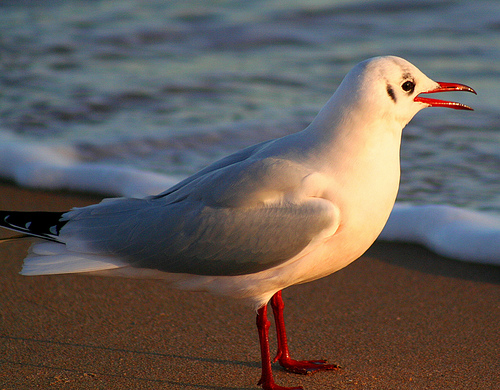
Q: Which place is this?
A: It is an ocean.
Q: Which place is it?
A: It is an ocean.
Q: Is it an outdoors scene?
A: Yes, it is outdoors.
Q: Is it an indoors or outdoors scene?
A: It is outdoors.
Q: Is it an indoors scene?
A: No, it is outdoors.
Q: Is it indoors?
A: No, it is outdoors.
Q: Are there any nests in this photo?
A: No, there are no nests.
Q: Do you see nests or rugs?
A: No, there are no nests or rugs.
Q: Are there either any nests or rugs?
A: No, there are no nests or rugs.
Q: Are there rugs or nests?
A: No, there are no nests or rugs.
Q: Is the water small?
A: Yes, the water is small.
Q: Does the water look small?
A: Yes, the water is small.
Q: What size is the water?
A: The water is small.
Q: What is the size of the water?
A: The water is small.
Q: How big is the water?
A: The water is small.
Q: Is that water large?
A: No, the water is small.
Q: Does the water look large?
A: No, the water is small.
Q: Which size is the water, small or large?
A: The water is small.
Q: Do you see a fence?
A: No, there are no fences.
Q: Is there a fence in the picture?
A: No, there are no fences.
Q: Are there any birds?
A: Yes, there is a bird.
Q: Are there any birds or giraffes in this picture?
A: Yes, there is a bird.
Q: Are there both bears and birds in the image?
A: No, there is a bird but no bears.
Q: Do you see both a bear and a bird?
A: No, there is a bird but no bears.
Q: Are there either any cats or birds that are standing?
A: Yes, the bird is standing.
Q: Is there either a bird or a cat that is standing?
A: Yes, the bird is standing.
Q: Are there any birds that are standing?
A: Yes, there is a bird that is standing.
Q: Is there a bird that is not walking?
A: Yes, there is a bird that is standing.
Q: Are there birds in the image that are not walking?
A: Yes, there is a bird that is standing.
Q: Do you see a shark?
A: No, there are no sharks.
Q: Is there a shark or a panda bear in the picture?
A: No, there are no sharks or pandas.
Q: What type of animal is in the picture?
A: The animal is a bird.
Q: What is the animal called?
A: The animal is a bird.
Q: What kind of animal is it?
A: The animal is a bird.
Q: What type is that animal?
A: This is a bird.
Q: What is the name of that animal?
A: This is a bird.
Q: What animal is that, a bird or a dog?
A: This is a bird.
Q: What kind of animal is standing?
A: The animal is a bird.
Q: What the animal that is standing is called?
A: The animal is a bird.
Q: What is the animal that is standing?
A: The animal is a bird.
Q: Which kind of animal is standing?
A: The animal is a bird.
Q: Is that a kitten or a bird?
A: That is a bird.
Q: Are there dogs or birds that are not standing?
A: No, there is a bird but it is standing.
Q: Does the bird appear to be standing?
A: Yes, the bird is standing.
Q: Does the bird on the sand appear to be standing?
A: Yes, the bird is standing.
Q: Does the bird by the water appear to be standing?
A: Yes, the bird is standing.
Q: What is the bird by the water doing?
A: The bird is standing.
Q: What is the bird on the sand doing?
A: The bird is standing.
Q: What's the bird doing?
A: The bird is standing.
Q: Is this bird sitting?
A: No, the bird is standing.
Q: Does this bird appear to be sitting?
A: No, the bird is standing.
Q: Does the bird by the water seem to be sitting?
A: No, the bird is standing.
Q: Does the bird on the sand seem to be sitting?
A: No, the bird is standing.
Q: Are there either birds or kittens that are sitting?
A: No, there is a bird but it is standing.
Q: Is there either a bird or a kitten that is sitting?
A: No, there is a bird but it is standing.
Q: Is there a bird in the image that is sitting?
A: No, there is a bird but it is standing.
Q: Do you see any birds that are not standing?
A: No, there is a bird but it is standing.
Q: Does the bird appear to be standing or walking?
A: The bird is standing.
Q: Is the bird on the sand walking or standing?
A: The bird is standing.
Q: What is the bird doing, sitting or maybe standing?
A: The bird is standing.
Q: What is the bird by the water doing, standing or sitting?
A: The bird is standing.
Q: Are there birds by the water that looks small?
A: Yes, there is a bird by the water.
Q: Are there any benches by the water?
A: No, there is a bird by the water.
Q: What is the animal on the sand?
A: The animal is a bird.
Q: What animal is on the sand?
A: The animal is a bird.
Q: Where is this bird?
A: The bird is on the sand.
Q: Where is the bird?
A: The bird is on the sand.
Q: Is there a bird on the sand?
A: Yes, there is a bird on the sand.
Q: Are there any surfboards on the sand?
A: No, there is a bird on the sand.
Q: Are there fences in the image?
A: No, there are no fences.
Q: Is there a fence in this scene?
A: No, there are no fences.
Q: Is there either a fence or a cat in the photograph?
A: No, there are no fences or cats.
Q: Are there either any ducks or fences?
A: No, there are no fences or ducks.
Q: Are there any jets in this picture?
A: No, there are no jets.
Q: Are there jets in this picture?
A: No, there are no jets.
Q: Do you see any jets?
A: No, there are no jets.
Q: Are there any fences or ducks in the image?
A: No, there are no fences or ducks.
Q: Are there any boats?
A: No, there are no boats.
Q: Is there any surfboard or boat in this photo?
A: No, there are no boats or surfboards.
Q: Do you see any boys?
A: No, there are no boys.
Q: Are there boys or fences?
A: No, there are no boys or fences.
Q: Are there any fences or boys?
A: No, there are no boys or fences.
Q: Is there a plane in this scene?
A: No, there are no airplanes.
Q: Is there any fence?
A: No, there are no fences.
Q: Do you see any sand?
A: Yes, there is sand.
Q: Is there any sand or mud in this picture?
A: Yes, there is sand.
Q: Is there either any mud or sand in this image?
A: Yes, there is sand.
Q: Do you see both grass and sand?
A: No, there is sand but no grass.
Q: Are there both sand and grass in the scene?
A: No, there is sand but no grass.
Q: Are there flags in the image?
A: No, there are no flags.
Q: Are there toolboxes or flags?
A: No, there are no flags or toolboxes.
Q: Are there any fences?
A: No, there are no fences.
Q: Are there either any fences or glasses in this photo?
A: No, there are no fences or glasses.